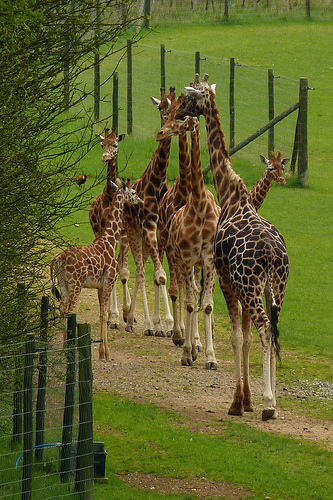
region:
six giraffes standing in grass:
[50, 71, 289, 416]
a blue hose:
[12, 441, 64, 470]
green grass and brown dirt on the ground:
[120, 415, 326, 498]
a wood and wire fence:
[72, 39, 312, 169]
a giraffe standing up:
[173, 84, 288, 416]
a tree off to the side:
[0, 0, 131, 373]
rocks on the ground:
[289, 371, 332, 402]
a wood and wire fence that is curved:
[0, 295, 108, 494]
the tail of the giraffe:
[261, 242, 282, 366]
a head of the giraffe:
[96, 127, 125, 160]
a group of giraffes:
[78, 60, 250, 211]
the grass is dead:
[182, 395, 271, 440]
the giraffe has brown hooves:
[221, 389, 283, 428]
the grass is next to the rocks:
[111, 405, 271, 498]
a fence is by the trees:
[7, 406, 134, 470]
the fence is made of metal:
[28, 394, 121, 495]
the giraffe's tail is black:
[47, 282, 88, 302]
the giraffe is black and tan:
[230, 224, 299, 279]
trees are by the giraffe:
[21, 155, 162, 353]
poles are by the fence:
[193, 67, 267, 157]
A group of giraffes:
[50, 72, 287, 417]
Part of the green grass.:
[188, 449, 224, 464]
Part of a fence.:
[42, 464, 76, 492]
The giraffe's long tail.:
[267, 247, 281, 361]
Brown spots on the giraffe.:
[229, 225, 257, 260]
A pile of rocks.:
[299, 379, 332, 396]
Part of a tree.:
[3, 194, 25, 251]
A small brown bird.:
[66, 173, 89, 187]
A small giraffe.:
[46, 176, 143, 361]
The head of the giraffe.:
[94, 128, 126, 163]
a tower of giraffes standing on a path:
[47, 70, 289, 422]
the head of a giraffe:
[92, 124, 127, 162]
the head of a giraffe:
[106, 174, 145, 208]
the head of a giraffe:
[168, 71, 223, 120]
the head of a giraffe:
[253, 146, 291, 186]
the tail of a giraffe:
[260, 240, 284, 370]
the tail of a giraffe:
[44, 256, 63, 301]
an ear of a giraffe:
[178, 79, 197, 95]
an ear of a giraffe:
[256, 146, 270, 166]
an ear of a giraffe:
[148, 93, 165, 110]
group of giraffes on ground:
[65, 72, 318, 451]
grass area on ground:
[115, 413, 319, 491]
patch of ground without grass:
[127, 469, 238, 494]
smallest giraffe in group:
[45, 183, 140, 340]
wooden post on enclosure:
[290, 71, 315, 187]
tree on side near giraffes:
[0, 5, 142, 375]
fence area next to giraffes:
[0, 344, 82, 496]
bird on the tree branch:
[62, 170, 91, 184]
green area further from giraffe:
[181, 28, 330, 60]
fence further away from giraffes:
[122, 6, 331, 24]